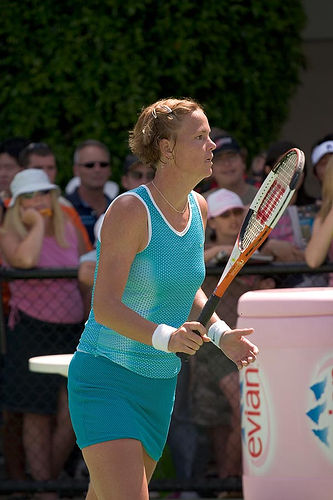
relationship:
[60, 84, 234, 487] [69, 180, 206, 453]
woman in blue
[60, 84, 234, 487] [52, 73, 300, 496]
woman playing tennis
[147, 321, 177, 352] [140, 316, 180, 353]
band on wrist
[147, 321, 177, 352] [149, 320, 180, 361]
band on wrist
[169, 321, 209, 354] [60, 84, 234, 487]
hand of woman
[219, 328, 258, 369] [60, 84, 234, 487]
hand of woman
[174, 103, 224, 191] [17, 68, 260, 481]
face of woman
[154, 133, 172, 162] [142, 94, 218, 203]
ear of woman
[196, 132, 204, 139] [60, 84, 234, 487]
eye of woman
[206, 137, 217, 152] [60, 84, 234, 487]
nose of woman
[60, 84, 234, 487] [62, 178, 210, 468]
woman wearing clothes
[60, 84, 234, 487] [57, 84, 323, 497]
woman playing tennis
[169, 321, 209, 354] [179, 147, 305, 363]
hand on tennis racket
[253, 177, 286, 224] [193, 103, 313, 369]
letter on racket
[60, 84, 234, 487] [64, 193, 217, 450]
woman wearing outfit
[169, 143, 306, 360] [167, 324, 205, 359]
tennis racquet in hand